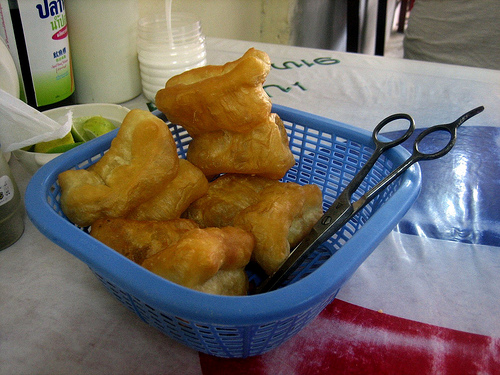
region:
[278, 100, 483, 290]
a pair of kitchen scissors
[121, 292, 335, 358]
a blue plastic basket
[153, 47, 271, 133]
an irregular fried donought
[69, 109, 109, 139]
some lime wedges in a bowl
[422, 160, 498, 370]
a red, white and blue table cloth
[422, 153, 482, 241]
a reflection of the flash from the camera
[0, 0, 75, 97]
a bottle of vanilla extract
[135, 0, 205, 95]
a bottle of cream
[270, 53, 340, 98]
green writing on the white table cloth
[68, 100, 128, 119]
a white bowl on the table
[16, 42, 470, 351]
a basket of fried food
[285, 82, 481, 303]
scissors in the basket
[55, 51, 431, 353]
the basket is blue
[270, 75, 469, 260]
the scissors are silver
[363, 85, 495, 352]
the tablecloth is plastic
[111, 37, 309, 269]
the fried food is golden brown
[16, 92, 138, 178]
a bowl of limes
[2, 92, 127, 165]
the bowl is small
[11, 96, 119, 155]
the limes are green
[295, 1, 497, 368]
the tablecloth is red, white, and blue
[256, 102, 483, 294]
pair of metal scissors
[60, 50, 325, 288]
several pieces of fried dough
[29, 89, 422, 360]
blue plastic basket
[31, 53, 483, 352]
fried dough and scissors in a blue plastic basket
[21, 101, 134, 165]
bowl of lime wedges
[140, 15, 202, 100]
jar or white paste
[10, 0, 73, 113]
bottle with blue and green writing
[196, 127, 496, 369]
red, white, and blue symbol on tablecloth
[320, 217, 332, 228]
screw in the pair of scissors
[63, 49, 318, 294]
four cooked brown pastries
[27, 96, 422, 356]
blue plastic basket on table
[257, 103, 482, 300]
metal scissors in basket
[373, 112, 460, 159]
holes in handle for fingers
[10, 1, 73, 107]
label on side of bottle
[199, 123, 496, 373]
red white and blue circle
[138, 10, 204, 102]
clear glass jar with ridges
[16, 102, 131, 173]
white bowl with green slices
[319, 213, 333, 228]
bolt on side of scissor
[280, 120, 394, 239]
holes in side of basket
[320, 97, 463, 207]
the scizzors are in the basket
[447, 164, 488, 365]
the table cloth is red white and blue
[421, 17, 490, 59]
the shirt is white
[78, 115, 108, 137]
lime is in a bowl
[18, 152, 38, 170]
the bowl is white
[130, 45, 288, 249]
the food is brown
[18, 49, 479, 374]
the food is next to the scizzors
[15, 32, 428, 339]
the food is in the basket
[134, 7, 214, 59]
milk is in the cup